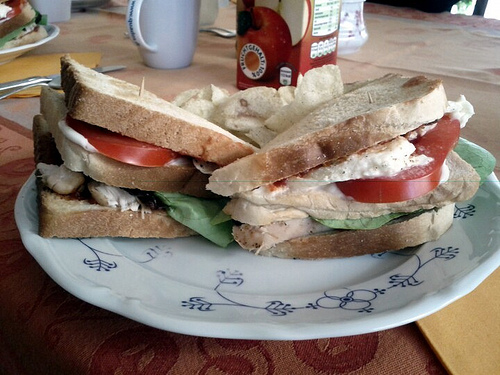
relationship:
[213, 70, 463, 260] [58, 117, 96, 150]
sandwich with mayonnaise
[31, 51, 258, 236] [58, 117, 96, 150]
sandwich with mayonnaise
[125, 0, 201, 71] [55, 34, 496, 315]
coffee cup on table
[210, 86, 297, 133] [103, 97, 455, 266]
chips by sandwich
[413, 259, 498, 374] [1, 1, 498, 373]
mat on table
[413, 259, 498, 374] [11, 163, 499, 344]
mat on plate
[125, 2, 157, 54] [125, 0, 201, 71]
handle on coffee cup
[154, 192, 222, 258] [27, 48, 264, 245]
lettuce on sandwich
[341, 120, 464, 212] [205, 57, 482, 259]
tomato on sandwich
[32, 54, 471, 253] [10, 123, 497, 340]
food on plate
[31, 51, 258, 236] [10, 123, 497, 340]
sandwich sitting plate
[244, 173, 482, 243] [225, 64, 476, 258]
chicken on sandwich